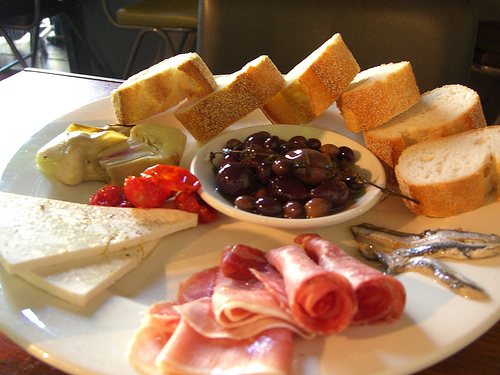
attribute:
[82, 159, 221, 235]
tomatoes — dried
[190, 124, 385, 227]
dish — white, ceramic, shiny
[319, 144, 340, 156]
olive — black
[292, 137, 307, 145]
olive — black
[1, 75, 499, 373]
dish — white, ceramic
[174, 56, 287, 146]
slice of bread — baguette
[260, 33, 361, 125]
slice of bread — chopped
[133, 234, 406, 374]
meat — rolled up, rolled, folded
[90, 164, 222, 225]
fruit — red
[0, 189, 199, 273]
cheese — sliced, white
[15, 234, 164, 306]
cheese — sliced, white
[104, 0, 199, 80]
chair — metal, yellow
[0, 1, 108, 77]
chair — metal